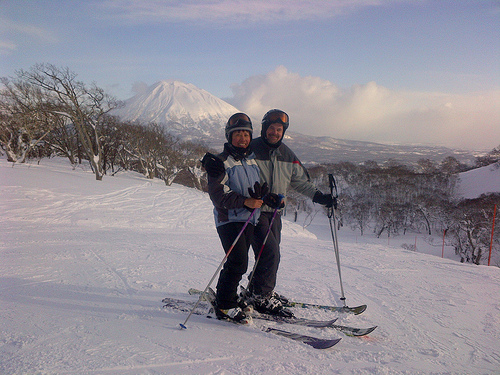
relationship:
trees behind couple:
[0, 64, 148, 184] [202, 104, 297, 324]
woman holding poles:
[209, 110, 283, 328] [177, 205, 279, 330]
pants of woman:
[207, 219, 248, 314] [209, 110, 283, 328]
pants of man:
[247, 208, 282, 297] [250, 108, 337, 318]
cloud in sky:
[299, 61, 446, 143] [5, 0, 495, 145]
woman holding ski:
[209, 110, 283, 328] [181, 208, 255, 331]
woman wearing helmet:
[209, 110, 283, 328] [219, 110, 252, 135]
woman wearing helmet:
[209, 110, 283, 328] [260, 105, 289, 131]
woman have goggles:
[209, 110, 283, 328] [226, 112, 251, 126]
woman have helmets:
[209, 110, 283, 328] [221, 111, 258, 152]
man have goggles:
[250, 108, 337, 318] [263, 110, 287, 122]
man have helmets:
[250, 108, 337, 318] [261, 105, 292, 145]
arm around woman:
[201, 142, 221, 172] [202, 114, 281, 327]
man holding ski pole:
[250, 108, 337, 318] [327, 171, 349, 304]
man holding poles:
[250, 108, 337, 318] [322, 201, 352, 312]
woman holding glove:
[209, 110, 283, 328] [245, 180, 271, 203]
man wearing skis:
[250, 108, 337, 318] [161, 300, 342, 350]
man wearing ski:
[250, 108, 337, 318] [191, 276, 371, 319]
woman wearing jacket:
[209, 110, 283, 328] [208, 141, 276, 228]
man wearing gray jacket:
[250, 108, 337, 318] [250, 141, 320, 214]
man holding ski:
[250, 108, 337, 318] [187, 287, 367, 314]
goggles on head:
[227, 110, 253, 130] [217, 112, 259, 159]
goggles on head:
[260, 108, 290, 125] [260, 110, 289, 145]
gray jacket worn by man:
[250, 136, 332, 218] [247, 99, 343, 329]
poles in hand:
[177, 205, 258, 332] [226, 185, 281, 212]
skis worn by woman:
[161, 300, 342, 350] [209, 110, 283, 328]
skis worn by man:
[172, 278, 379, 348] [252, 100, 310, 342]